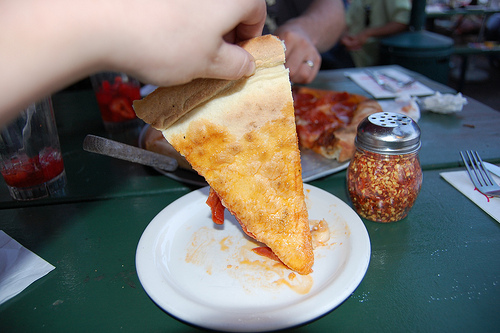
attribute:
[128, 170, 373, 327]
plate — White 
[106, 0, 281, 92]
hand — Light 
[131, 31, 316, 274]
pizza — Held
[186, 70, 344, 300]
pizza — cooked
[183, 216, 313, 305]
juice — Orange 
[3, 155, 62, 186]
beverage — almost gone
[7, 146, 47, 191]
liquid — Red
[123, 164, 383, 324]
plate — White 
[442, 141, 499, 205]
fork — Silver 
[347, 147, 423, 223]
flakes — Red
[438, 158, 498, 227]
paper napkin — White 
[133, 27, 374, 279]
pizza — Yellow 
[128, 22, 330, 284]
slice — almost upside down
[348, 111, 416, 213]
container — Clear 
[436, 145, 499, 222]
fork — Silver 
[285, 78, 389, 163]
slices — remaining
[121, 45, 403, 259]
pizza — Held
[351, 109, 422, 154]
top — silver